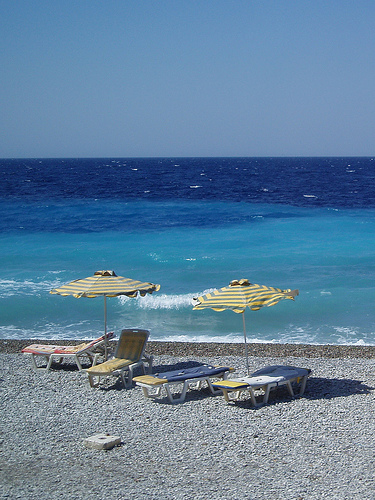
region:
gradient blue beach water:
[122, 187, 190, 258]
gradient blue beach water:
[142, 203, 210, 265]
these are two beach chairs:
[145, 354, 309, 409]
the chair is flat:
[224, 353, 301, 413]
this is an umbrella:
[186, 275, 293, 323]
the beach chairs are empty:
[136, 357, 300, 399]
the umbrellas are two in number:
[51, 263, 292, 314]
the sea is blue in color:
[197, 157, 301, 202]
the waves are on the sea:
[163, 279, 184, 316]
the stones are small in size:
[208, 420, 310, 498]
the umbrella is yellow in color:
[236, 287, 261, 302]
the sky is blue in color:
[128, 37, 270, 128]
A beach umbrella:
[189, 262, 300, 419]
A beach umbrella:
[145, 224, 336, 365]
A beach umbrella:
[148, 257, 372, 452]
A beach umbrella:
[150, 215, 266, 442]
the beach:
[1, 154, 370, 489]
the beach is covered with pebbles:
[0, 333, 373, 498]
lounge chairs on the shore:
[28, 268, 322, 418]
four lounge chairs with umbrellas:
[22, 260, 321, 414]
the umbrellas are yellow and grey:
[49, 267, 302, 375]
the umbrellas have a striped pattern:
[49, 270, 278, 387]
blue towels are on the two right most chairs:
[130, 354, 314, 410]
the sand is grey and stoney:
[2, 335, 373, 495]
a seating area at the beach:
[21, 240, 357, 435]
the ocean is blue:
[9, 158, 372, 346]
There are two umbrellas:
[59, 261, 307, 390]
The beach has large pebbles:
[32, 321, 355, 479]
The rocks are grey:
[23, 327, 347, 474]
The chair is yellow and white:
[75, 329, 162, 390]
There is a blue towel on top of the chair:
[148, 347, 215, 401]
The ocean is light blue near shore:
[78, 170, 329, 283]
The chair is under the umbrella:
[65, 269, 157, 380]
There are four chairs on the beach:
[21, 313, 319, 415]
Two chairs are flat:
[137, 346, 318, 406]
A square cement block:
[80, 427, 118, 450]